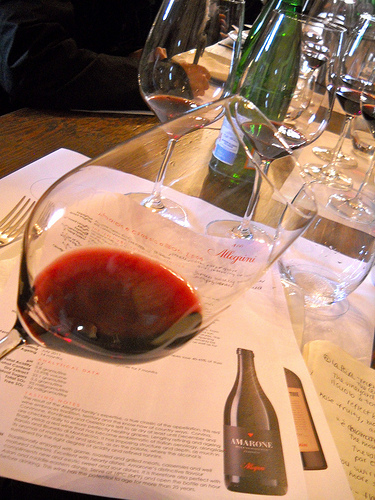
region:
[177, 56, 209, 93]
part of a glass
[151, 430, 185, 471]
part of a paper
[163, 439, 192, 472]
part of a paper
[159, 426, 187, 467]
aprt of a aper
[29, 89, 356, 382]
a picture about wine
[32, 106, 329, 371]
a wine glass with red wine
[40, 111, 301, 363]
red wine in a glass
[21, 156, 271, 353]
wine for tasting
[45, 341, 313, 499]
information about this type of wine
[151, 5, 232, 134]
wine glasses on the table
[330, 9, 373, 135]
these wine glasses have wine in them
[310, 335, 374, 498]
notes about different types of wine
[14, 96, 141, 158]
a wooden table in the scene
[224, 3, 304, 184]
a green bottle on the table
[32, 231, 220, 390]
red wine in the glass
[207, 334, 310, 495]
picture on the paper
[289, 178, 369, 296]
empty glass on the table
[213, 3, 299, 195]
green bottle on the table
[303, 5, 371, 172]
several glasses with wine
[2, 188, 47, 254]
fork next to wine glass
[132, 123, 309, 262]
stems on the wine glasses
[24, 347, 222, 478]
writing on the paper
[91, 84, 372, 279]
glasses on the table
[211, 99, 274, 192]
sticker on the bottle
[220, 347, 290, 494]
A black wine bottle picture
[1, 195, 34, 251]
A metal fork on a table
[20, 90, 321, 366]
A glass of wine with red wine in it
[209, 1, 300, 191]
A green glass bottle on a table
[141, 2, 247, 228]
A wine glass sitting on a table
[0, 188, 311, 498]
A menu with wine information on it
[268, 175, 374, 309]
A small glass cup on a table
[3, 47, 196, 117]
A black leather book for credit cards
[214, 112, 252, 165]
A label on a green bottle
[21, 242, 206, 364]
A small amount of red wine